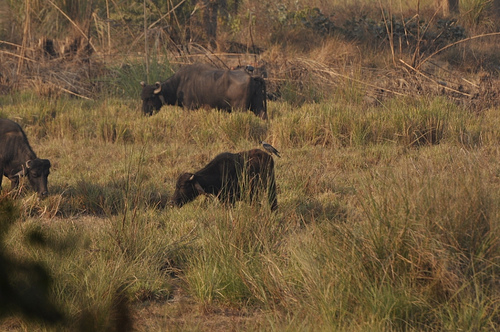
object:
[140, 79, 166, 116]
head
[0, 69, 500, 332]
ground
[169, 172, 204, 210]
head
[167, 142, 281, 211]
adult steer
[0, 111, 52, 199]
adult steer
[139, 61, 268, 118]
adult steer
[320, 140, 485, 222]
patch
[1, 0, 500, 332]
grasslands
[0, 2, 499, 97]
branches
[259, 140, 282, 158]
bird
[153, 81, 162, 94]
horn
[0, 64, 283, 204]
family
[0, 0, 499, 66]
bushes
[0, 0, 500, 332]
landscape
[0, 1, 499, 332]
grass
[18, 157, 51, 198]
head